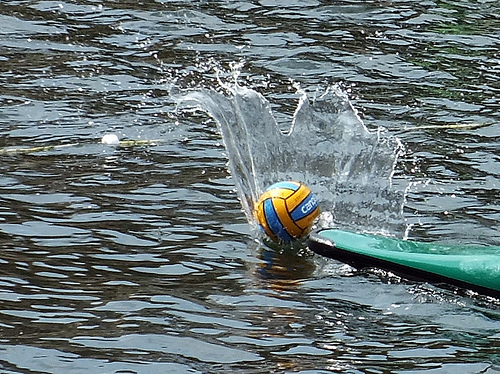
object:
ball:
[253, 181, 318, 246]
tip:
[306, 225, 338, 248]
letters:
[298, 204, 308, 214]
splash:
[167, 67, 406, 242]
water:
[0, 0, 500, 373]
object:
[306, 226, 499, 292]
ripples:
[0, 0, 500, 372]